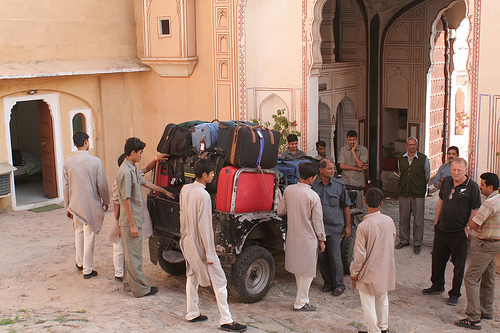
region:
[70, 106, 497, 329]
people standing near an old vehicle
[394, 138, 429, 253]
man has his hands behind his back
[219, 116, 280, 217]
bags luggage on back of vehicle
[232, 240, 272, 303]
tire of vehicle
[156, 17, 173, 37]
small window in the wall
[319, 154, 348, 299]
man wearing blue uniform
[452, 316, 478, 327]
guy wearing black sandals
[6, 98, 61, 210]
door of building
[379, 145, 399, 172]
red planters pot.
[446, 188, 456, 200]
man carrying glasses on his shirt.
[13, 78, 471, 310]
several people standing around a jeep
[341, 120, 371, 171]
a man with his hand to his face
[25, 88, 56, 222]
a open door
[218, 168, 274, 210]
a red suitcase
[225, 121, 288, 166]
a black suitcase with brown handles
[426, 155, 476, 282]
a man wearing black clothing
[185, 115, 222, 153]
a blue suitcase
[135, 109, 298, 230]
a vehicle loaded with luggage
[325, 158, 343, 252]
a man wearing grey clothing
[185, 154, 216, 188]
a man with black hair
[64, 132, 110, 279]
a man wearing a beige shirt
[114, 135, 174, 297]
a man in olive green coveralls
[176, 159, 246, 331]
a man in a white shirt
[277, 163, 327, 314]
a man in a beige shirt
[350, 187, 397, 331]
a man in a beige shirt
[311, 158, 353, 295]
a man in a blue shirt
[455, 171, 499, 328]
a man in a beige shirt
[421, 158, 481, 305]
a man in a black shirt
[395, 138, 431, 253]
a man in a brown vest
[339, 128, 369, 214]
a man in a beige shirt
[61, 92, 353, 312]
people on the ground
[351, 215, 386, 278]
tan shirt on person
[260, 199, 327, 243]
tan shirt on person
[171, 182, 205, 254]
tan shirt on person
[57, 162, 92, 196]
tan shirt on person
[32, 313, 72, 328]
grass on the ground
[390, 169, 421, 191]
the shirt is greren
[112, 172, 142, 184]
the shirt is green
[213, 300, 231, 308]
the pants are white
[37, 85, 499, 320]
several people standing in the street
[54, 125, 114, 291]
a man standing in the street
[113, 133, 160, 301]
a man standing in the street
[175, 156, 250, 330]
a man standing in the street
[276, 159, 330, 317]
a man standing in the street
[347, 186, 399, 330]
a man standing in the street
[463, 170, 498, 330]
a man standing in the street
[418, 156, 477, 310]
a man standing in the street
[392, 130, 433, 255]
a man standing in the street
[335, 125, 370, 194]
a man standing in the street